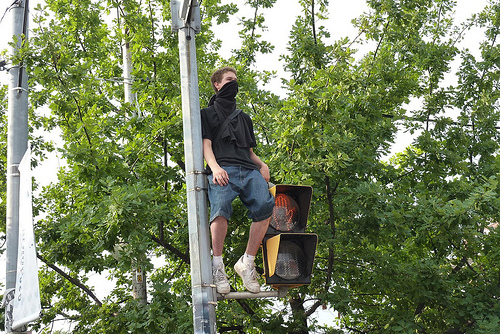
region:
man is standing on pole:
[180, 52, 270, 299]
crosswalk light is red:
[263, 184, 315, 286]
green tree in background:
[0, 1, 498, 333]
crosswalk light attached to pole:
[155, 0, 344, 332]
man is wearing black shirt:
[198, 66, 271, 293]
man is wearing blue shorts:
[200, 66, 273, 295]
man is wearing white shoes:
[198, 67, 276, 292]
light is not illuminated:
[261, 231, 317, 285]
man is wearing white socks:
[200, 66, 274, 295]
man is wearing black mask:
[200, 67, 272, 292]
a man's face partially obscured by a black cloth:
[215, 65, 242, 99]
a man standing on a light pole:
[196, 70, 268, 295]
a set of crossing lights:
[275, 182, 315, 286]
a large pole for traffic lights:
[173, 0, 220, 330]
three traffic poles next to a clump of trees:
[1, 2, 206, 332]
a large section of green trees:
[305, 9, 487, 254]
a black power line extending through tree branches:
[382, 109, 498, 129]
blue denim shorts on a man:
[208, 162, 274, 232]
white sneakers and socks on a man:
[211, 249, 260, 297]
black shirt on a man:
[201, 97, 253, 154]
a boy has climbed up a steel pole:
[176, 66, 271, 305]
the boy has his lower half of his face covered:
[198, 77, 259, 171]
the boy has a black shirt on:
[206, 67, 258, 174]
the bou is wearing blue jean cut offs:
[203, 161, 273, 226]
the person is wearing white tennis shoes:
[216, 260, 260, 295]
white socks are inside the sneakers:
[212, 247, 258, 267]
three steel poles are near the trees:
[5, 4, 218, 332]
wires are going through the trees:
[8, 63, 499, 150]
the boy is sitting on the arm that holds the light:
[198, 70, 319, 294]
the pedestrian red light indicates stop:
[215, 181, 313, 298]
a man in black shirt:
[174, 56, 337, 294]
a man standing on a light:
[184, 75, 314, 315]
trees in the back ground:
[380, 75, 449, 252]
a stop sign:
[259, 179, 341, 241]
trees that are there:
[73, 104, 215, 317]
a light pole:
[182, 37, 254, 331]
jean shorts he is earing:
[163, 146, 313, 235]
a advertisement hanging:
[21, 137, 66, 318]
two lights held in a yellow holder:
[237, 174, 346, 311]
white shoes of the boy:
[209, 254, 301, 309]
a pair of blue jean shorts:
[207, 163, 274, 223]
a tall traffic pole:
[164, 1, 226, 333]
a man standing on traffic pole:
[203, 66, 264, 292]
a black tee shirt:
[199, 105, 257, 172]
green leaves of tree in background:
[305, 93, 362, 165]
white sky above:
[337, 5, 354, 23]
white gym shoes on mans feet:
[211, 256, 263, 294]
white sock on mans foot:
[243, 253, 257, 265]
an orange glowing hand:
[268, 193, 298, 228]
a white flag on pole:
[11, 144, 43, 326]